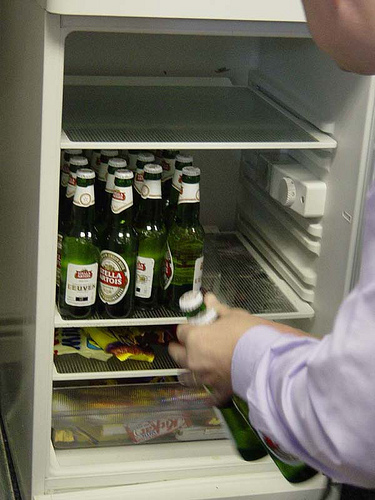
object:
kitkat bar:
[126, 413, 184, 441]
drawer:
[51, 374, 229, 443]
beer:
[56, 147, 206, 320]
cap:
[181, 166, 200, 176]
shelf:
[58, 72, 345, 152]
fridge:
[0, 1, 375, 500]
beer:
[176, 290, 268, 462]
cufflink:
[232, 319, 298, 407]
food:
[53, 324, 165, 363]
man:
[166, 0, 373, 498]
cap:
[142, 163, 163, 175]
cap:
[114, 168, 134, 180]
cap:
[76, 168, 96, 180]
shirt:
[229, 169, 374, 491]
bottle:
[157, 165, 204, 313]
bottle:
[129, 162, 169, 310]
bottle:
[94, 169, 136, 321]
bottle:
[59, 164, 99, 321]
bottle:
[168, 152, 193, 228]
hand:
[164, 292, 256, 408]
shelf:
[52, 226, 317, 331]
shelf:
[51, 332, 188, 385]